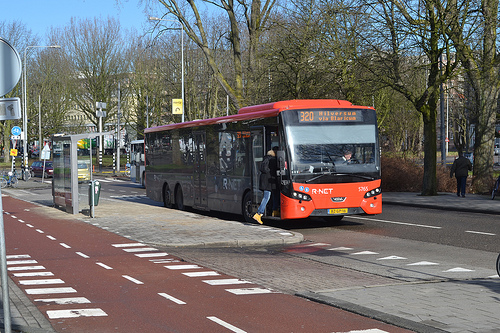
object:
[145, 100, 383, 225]
bus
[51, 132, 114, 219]
bus shelter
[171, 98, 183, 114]
traffic sign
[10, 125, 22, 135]
traffic sign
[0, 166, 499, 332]
city street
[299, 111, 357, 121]
digital sign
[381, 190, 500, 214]
sidewalk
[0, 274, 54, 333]
sidewalk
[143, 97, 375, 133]
roof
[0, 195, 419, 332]
surface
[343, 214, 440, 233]
lines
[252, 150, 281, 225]
person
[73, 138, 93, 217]
glass wall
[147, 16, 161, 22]
street light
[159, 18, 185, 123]
pole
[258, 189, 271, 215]
leg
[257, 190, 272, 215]
jeans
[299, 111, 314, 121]
number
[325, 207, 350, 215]
license plate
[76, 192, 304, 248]
curb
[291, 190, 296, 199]
headlights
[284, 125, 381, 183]
windshield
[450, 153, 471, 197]
person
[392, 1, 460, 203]
trees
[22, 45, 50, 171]
pole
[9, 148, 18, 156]
sign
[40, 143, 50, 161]
sign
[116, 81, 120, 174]
pole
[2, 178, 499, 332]
lines